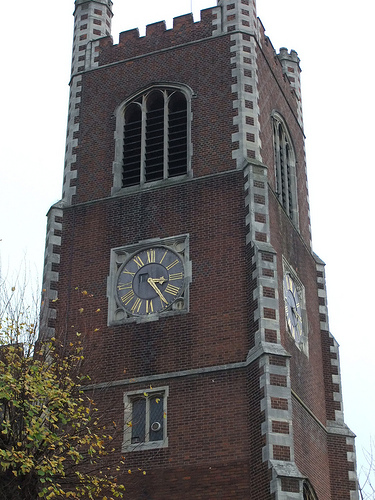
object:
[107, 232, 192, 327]
clock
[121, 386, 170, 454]
window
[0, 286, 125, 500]
tree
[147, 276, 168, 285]
clock hand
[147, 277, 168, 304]
clock hand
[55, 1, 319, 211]
tower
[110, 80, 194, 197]
window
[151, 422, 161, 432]
object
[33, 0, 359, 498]
building